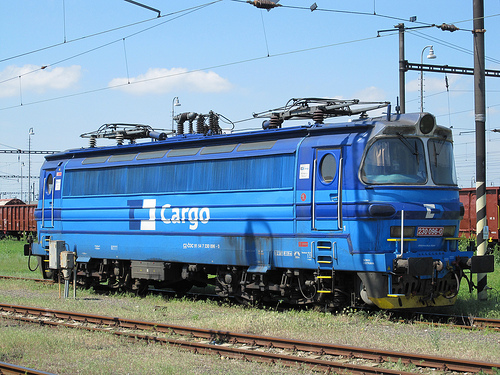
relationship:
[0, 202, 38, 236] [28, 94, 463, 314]
car behind train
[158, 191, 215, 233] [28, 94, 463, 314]
cargo on train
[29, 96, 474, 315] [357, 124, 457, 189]
train has windshield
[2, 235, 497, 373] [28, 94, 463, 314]
grass beside train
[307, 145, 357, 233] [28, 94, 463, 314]
door on train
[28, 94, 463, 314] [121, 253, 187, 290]
train has engine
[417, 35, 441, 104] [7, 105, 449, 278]
lightpost behind train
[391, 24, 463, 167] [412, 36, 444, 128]
lamp on light pole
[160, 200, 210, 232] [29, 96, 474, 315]
"cargo" on train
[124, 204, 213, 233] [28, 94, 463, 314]
cargo logo on train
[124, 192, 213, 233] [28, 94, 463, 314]
cargo logo on train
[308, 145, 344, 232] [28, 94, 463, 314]
door on train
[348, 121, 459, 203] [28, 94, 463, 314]
windshield on train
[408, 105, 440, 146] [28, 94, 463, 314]
headlight on train